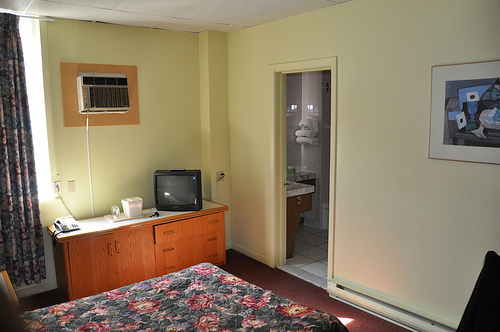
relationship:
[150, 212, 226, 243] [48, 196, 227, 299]
drawer on dresser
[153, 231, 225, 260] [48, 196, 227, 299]
drawer on dresser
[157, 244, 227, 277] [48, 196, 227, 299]
drawer on dresser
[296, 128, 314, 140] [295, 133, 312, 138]
towel on shelf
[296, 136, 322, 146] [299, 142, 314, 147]
towels on shelf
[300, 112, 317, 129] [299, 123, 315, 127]
towel on shelf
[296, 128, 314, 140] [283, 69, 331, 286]
towel in bathroom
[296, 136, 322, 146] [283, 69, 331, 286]
towels in bathroom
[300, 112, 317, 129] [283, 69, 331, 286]
towel in bathroom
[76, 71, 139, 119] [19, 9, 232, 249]
air conditioner in wall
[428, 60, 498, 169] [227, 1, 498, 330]
artwork on wall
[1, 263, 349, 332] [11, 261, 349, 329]
design on bed spread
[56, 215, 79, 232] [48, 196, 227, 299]
telephone on dresser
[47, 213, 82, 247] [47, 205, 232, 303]
telephone on drawer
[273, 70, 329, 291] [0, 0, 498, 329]
bathroom attached to bedroom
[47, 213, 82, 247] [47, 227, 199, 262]
telephone on stand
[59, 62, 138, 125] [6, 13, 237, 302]
air conditioner in wall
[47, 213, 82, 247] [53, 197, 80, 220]
telephone with cord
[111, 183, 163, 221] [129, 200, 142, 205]
container for ice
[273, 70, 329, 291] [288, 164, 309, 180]
bathroom with sink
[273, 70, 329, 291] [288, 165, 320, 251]
bathroom with counter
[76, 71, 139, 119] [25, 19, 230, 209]
air conditioner mounted on wall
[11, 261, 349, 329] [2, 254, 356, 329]
bed spread on bed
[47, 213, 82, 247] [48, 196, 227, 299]
telephone on dresser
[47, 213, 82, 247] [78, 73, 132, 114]
telephone below air conditioner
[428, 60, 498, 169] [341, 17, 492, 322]
artwork on wall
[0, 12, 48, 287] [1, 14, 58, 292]
curtain hanging on window